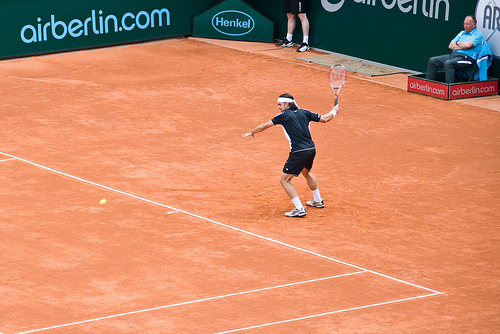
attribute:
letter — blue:
[102, 11, 121, 38]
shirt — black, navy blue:
[269, 109, 321, 152]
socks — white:
[275, 183, 347, 233]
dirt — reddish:
[1, 39, 498, 332]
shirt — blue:
[449, 29, 490, 61]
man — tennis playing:
[241, 90, 341, 216]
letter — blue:
[135, 10, 149, 29]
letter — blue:
[140, 2, 182, 30]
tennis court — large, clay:
[2, 35, 498, 332]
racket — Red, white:
[317, 55, 354, 118]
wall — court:
[0, 6, 492, 85]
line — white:
[16, 263, 370, 331]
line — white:
[215, 287, 443, 332]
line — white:
[6, 153, 441, 298]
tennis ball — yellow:
[99, 196, 109, 206]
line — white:
[182, 239, 457, 319]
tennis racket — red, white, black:
[304, 50, 384, 152]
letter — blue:
[59, 17, 89, 37]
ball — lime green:
[94, 192, 111, 208]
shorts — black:
[281, 145, 316, 174]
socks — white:
[251, 195, 344, 232]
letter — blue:
[119, 9, 137, 31]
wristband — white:
[329, 109, 339, 117]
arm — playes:
[299, 103, 340, 122]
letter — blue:
[13, 20, 45, 52]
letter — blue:
[88, 4, 110, 44]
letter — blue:
[151, 0, 177, 30]